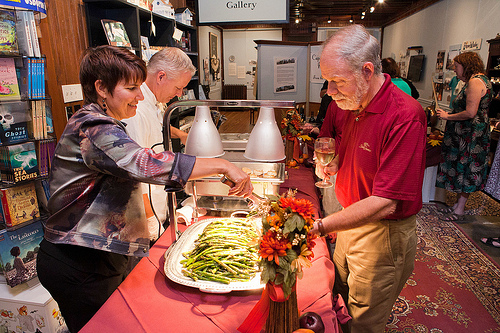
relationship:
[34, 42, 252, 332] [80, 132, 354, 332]
person standing at a table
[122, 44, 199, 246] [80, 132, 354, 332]
person standing at a table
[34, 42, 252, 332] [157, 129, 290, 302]
person standing at a buffet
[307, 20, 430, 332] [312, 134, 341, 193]
man holding wine glass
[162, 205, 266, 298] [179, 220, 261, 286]
plate full of food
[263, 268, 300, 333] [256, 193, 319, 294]
vase full of flowers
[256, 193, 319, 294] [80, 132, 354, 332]
flowers on top of table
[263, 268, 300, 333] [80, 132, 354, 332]
vase on top of table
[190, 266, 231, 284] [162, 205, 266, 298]
asparagus on top of plate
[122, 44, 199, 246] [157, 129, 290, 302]
person setting up buffet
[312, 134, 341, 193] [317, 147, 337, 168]
wine glass full of white wine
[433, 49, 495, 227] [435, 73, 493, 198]
woman wearing dress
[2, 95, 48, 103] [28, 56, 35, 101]
rack filled with book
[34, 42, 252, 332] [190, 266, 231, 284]
person serving asparagus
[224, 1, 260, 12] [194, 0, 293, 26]
gallery written on sign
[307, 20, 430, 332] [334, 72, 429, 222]
man wearing shirt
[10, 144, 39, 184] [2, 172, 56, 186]
book placed on a shelf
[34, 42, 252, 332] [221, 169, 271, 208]
person holding tongs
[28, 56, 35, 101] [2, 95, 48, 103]
book placed on a rack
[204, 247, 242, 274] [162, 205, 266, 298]
asparagus served on a plate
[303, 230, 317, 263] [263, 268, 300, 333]
flower placed in a vase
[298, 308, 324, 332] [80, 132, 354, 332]
apple on top of table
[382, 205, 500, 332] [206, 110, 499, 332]
carpet on top of floor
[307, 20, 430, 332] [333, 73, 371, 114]
man has a beard